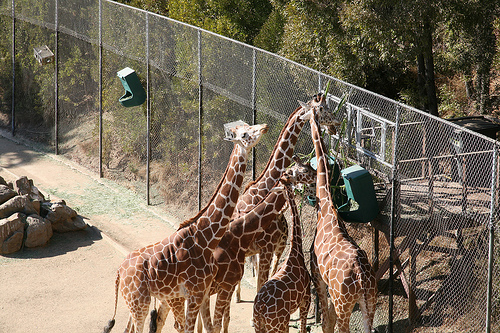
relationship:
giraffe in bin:
[225, 82, 340, 227] [111, 62, 146, 111]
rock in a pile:
[0, 178, 92, 255] [0, 173, 90, 256]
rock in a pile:
[22, 214, 59, 247] [0, 173, 90, 256]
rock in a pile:
[0, 216, 24, 255] [0, 173, 90, 256]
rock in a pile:
[0, 191, 40, 216] [0, 173, 90, 256]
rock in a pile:
[47, 204, 89, 236] [0, 173, 90, 256]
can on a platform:
[447, 111, 493, 188] [357, 148, 497, 238]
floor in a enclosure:
[0, 137, 310, 329] [3, 6, 498, 332]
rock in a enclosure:
[22, 214, 59, 247] [3, 6, 498, 332]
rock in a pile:
[22, 214, 59, 247] [2, 177, 108, 256]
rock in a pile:
[0, 216, 24, 255] [2, 177, 108, 256]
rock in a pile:
[47, 204, 89, 236] [2, 177, 108, 256]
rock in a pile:
[16, 175, 38, 190] [2, 177, 108, 256]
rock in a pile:
[0, 179, 22, 198] [2, 177, 108, 256]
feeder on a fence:
[112, 61, 152, 110] [1, 4, 499, 331]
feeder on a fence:
[339, 159, 391, 213] [1, 4, 499, 331]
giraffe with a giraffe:
[102, 118, 267, 331] [149, 154, 316, 331]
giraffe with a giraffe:
[153, 92, 336, 331] [260, 168, 323, 331]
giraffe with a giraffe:
[260, 168, 323, 331] [295, 102, 385, 320]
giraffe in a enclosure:
[233, 93, 336, 304] [3, 6, 498, 332]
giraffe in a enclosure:
[253, 174, 314, 333] [3, 6, 498, 332]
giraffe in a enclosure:
[100, 119, 269, 332] [3, 6, 498, 332]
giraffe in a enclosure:
[295, 95, 376, 332] [3, 6, 498, 332]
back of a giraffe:
[317, 214, 367, 260] [299, 100, 388, 328]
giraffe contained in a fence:
[233, 93, 336, 304] [0, 24, 482, 276]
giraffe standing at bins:
[253, 174, 314, 333] [336, 164, 379, 224]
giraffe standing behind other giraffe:
[295, 95, 376, 332] [253, 169, 311, 331]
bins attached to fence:
[318, 153, 371, 214] [1, 4, 499, 331]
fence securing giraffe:
[1, 4, 499, 331] [102, 118, 267, 331]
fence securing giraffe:
[1, 4, 499, 331] [201, 90, 326, 327]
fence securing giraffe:
[1, 4, 499, 331] [250, 160, 310, 329]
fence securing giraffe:
[1, 4, 499, 331] [310, 98, 376, 330]